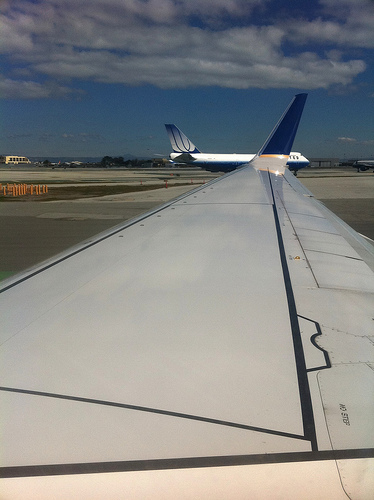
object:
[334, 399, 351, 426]
words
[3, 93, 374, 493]
plane wing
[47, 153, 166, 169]
mountains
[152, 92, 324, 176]
airplane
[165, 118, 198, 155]
tail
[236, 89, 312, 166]
tip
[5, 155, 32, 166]
bus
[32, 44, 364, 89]
cloud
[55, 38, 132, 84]
cloud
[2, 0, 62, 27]
cloud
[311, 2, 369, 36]
cloud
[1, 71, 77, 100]
cloud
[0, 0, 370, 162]
sky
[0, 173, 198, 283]
concrete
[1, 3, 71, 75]
section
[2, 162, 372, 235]
tarmac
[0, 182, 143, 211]
ground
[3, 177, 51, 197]
poles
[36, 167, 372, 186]
runway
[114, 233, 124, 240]
bolt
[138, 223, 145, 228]
bolt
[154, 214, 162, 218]
bolt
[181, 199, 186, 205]
bolt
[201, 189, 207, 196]
bolt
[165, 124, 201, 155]
logo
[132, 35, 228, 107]
section